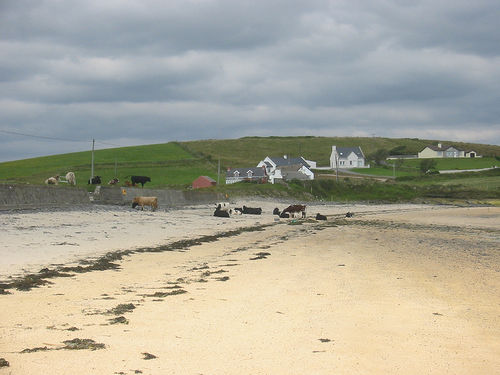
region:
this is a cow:
[124, 185, 174, 222]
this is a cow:
[124, 162, 161, 194]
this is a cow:
[89, 162, 113, 199]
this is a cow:
[61, 162, 79, 199]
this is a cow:
[36, 156, 70, 198]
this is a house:
[324, 134, 376, 182]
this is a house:
[258, 133, 323, 212]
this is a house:
[221, 157, 268, 197]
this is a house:
[412, 127, 495, 190]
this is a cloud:
[199, 45, 261, 121]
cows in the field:
[106, 179, 353, 234]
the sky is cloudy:
[25, 24, 363, 105]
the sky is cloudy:
[50, 31, 468, 153]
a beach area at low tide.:
[1, 190, 493, 370]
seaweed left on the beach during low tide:
[1, 217, 283, 296]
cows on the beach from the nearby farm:
[125, 193, 330, 231]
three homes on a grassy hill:
[0, 125, 487, 189]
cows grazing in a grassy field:
[32, 156, 168, 189]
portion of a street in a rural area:
[374, 161, 494, 185]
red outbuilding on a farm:
[188, 173, 223, 195]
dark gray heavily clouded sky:
[2, 1, 485, 132]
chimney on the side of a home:
[329, 143, 339, 173]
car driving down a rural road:
[420, 165, 440, 175]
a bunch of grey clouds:
[161, 25, 249, 99]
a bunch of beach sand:
[311, 248, 411, 330]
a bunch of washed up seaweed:
[90, 292, 151, 330]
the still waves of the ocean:
[40, 222, 84, 256]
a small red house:
[190, 169, 218, 197]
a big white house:
[251, 149, 311, 187]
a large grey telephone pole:
[64, 131, 109, 183]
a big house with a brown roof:
[418, 139, 479, 161]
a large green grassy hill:
[144, 136, 208, 173]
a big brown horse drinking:
[121, 189, 156, 214]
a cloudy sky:
[0, 1, 499, 162]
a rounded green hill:
[1, 134, 498, 213]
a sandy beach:
[0, 204, 497, 373]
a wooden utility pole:
[88, 135, 99, 183]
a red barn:
[188, 171, 217, 191]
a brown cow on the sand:
[130, 195, 162, 211]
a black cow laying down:
[213, 204, 230, 220]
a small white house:
[327, 141, 370, 171]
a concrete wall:
[0, 187, 218, 213]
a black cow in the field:
[130, 172, 150, 186]